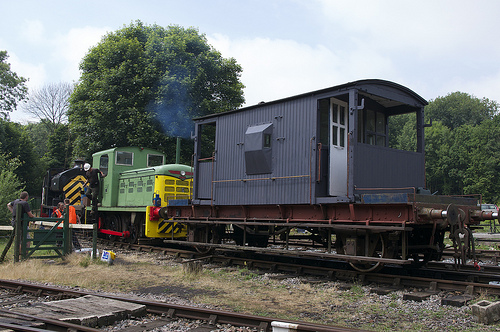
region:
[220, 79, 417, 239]
black engine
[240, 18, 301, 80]
white clouds in blue sky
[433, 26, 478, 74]
white clouds in blue sky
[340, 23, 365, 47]
white clouds in blue sky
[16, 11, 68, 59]
white clouds in blue sky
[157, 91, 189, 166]
smoke coming from stack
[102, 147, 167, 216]
the train is green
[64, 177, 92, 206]
the signs are black and yellow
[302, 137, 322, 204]
the railings are red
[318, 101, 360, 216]
door on the train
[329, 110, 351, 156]
windows on the door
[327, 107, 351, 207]
the door is white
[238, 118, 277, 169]
box on the train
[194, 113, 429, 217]
the train is blue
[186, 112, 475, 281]
train on the tracks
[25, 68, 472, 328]
A train engine has a caboose attached to the front of it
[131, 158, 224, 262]
Train engine is painted yellow in the front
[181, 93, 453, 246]
Caboose has a door on it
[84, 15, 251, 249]
Large tree towers above the train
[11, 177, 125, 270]
Men are working next to the train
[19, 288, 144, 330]
wood boards are in between the tracks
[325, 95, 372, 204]
White door has a four paned window in it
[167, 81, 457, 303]
Caboose is very short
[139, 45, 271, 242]
Smoke is rising from the train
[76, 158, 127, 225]
Man is hanging on the side of the train engine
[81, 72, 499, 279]
green and grey train on train tracks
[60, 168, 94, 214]
yellow arrows on back of black train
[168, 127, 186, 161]
chimney on top of green train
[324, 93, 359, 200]
white door on train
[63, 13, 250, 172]
tall green tree next to train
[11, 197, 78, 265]
green fence partition next to train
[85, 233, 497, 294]
brown metal train tracks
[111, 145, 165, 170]
window on front of green train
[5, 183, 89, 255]
people standing next to train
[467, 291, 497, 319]
cinderblock on ground next to train tracks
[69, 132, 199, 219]
green and yellow engine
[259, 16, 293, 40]
white clouds in blue sky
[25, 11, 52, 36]
white clouds in blue sky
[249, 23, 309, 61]
white clouds in blue sky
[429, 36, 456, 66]
white clouds in blue sky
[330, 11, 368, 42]
white clouds in blue sky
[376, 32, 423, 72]
white clouds in blue sky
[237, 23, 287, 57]
white clouds in blue sky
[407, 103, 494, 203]
green tree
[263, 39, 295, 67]
white clouds in blue sky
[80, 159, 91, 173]
A white hardhat on a man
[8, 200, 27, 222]
A black t-shirt on a man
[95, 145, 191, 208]
A green train car on a track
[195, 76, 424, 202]
A dark gray car on a train